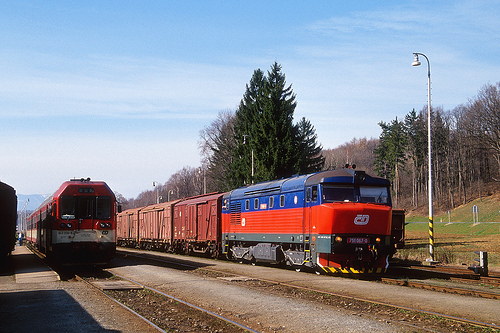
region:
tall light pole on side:
[395, 38, 455, 280]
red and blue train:
[192, 162, 421, 277]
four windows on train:
[236, 191, 302, 220]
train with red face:
[35, 167, 155, 275]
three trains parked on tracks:
[0, 151, 409, 301]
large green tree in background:
[210, 62, 342, 170]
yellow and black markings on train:
[320, 260, 401, 286]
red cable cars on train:
[120, 184, 247, 267]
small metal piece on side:
[463, 243, 496, 284]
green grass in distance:
[447, 195, 490, 237]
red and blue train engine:
[212, 158, 404, 283]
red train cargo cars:
[130, 191, 222, 253]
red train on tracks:
[31, 180, 134, 283]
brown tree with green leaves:
[181, 55, 333, 166]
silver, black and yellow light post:
[398, 42, 461, 262]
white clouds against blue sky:
[15, 41, 177, 138]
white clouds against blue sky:
[308, 40, 393, 113]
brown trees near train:
[438, 92, 490, 187]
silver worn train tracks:
[25, 275, 292, 325]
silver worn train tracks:
[398, 272, 480, 317]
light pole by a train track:
[406, 46, 442, 273]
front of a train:
[50, 173, 125, 265]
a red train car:
[136, 199, 176, 249]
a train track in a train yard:
[106, 275, 207, 331]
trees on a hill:
[435, 140, 497, 210]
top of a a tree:
[230, 58, 299, 109]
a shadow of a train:
[101, 242, 223, 274]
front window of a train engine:
[318, 178, 398, 202]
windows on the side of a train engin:
[238, 195, 297, 210]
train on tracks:
[19, 168, 136, 275]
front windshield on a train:
[316, 178, 394, 211]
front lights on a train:
[94, 218, 116, 235]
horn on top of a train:
[336, 158, 364, 174]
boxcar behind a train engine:
[166, 186, 237, 263]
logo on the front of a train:
[347, 208, 376, 229]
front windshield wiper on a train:
[371, 188, 390, 207]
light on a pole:
[401, 43, 444, 81]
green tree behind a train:
[216, 42, 337, 193]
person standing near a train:
[11, 225, 31, 249]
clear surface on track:
[143, 268, 232, 298]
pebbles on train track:
[132, 287, 197, 324]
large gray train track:
[89, 279, 218, 312]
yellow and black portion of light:
[420, 209, 455, 256]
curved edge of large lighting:
[408, 49, 443, 94]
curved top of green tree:
[222, 62, 334, 159]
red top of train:
[55, 172, 125, 216]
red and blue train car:
[226, 173, 414, 291]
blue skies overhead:
[102, 10, 194, 69]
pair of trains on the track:
[47, 151, 428, 273]